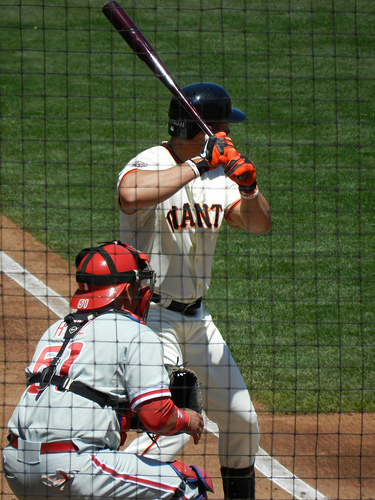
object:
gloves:
[222, 123, 263, 194]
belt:
[152, 292, 203, 314]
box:
[28, 364, 55, 391]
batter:
[119, 82, 270, 498]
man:
[114, 77, 274, 498]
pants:
[124, 296, 258, 469]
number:
[24, 340, 83, 394]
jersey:
[0, 312, 213, 498]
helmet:
[168, 83, 247, 135]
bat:
[101, 1, 212, 143]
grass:
[21, 18, 102, 127]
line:
[0, 0, 374, 499]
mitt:
[167, 364, 204, 413]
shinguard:
[155, 459, 221, 482]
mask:
[69, 238, 155, 320]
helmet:
[70, 238, 158, 314]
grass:
[256, 286, 372, 359]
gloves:
[199, 129, 236, 166]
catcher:
[3, 239, 213, 494]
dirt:
[331, 474, 353, 495]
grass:
[269, 64, 370, 121]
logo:
[168, 202, 220, 231]